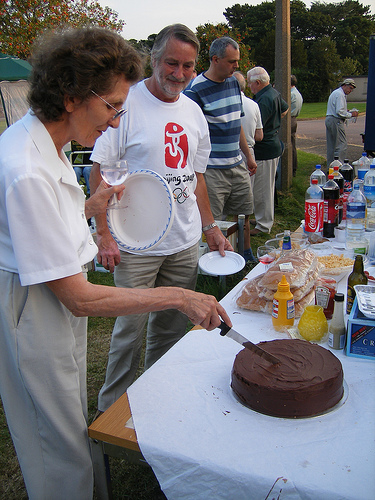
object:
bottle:
[344, 183, 368, 252]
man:
[90, 24, 230, 415]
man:
[323, 73, 357, 161]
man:
[288, 75, 302, 175]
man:
[255, 66, 288, 230]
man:
[239, 69, 262, 171]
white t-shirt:
[89, 81, 210, 255]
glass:
[99, 162, 128, 208]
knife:
[218, 319, 275, 365]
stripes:
[194, 81, 240, 161]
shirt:
[199, 73, 245, 161]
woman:
[1, 27, 234, 497]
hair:
[207, 37, 243, 60]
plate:
[199, 251, 245, 274]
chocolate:
[229, 339, 343, 419]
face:
[68, 76, 131, 147]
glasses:
[91, 90, 128, 118]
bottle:
[328, 294, 346, 350]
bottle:
[305, 178, 323, 242]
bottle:
[324, 174, 339, 238]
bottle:
[332, 166, 345, 183]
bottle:
[340, 160, 353, 183]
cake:
[231, 338, 348, 420]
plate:
[103, 167, 175, 252]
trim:
[105, 167, 174, 251]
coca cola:
[304, 201, 322, 231]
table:
[102, 184, 374, 461]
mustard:
[273, 275, 293, 331]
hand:
[95, 157, 130, 210]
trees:
[223, 2, 370, 102]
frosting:
[231, 337, 346, 420]